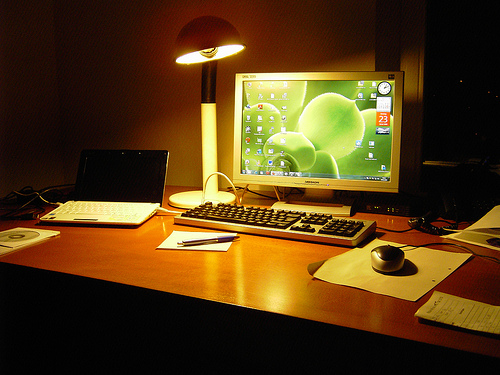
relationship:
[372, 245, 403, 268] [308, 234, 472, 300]
mouse on top of paper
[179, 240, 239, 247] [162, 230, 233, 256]
pen on top of paper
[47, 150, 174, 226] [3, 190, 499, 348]
laptop on desk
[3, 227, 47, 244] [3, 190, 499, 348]
cd on desk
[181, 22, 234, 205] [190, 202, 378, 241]
lamp shining on keyboard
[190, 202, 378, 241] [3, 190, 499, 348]
keyboard on desk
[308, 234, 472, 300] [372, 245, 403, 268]
paper under mouse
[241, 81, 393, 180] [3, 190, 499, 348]
computer on desk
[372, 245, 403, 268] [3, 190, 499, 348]
mouse on desk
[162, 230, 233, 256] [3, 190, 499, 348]
notebook on desk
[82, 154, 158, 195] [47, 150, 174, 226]
screen on laptop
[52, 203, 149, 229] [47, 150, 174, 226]
keyboard on laptop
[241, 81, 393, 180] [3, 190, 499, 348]
monitor on desk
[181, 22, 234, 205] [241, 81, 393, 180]
lamp over desktop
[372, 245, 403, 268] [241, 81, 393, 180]
mouse in front of desktop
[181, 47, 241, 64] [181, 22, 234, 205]
light on lamp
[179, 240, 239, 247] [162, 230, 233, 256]
pen on notebook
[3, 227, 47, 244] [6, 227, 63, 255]
cd in white case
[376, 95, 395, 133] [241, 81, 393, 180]
calender on desktop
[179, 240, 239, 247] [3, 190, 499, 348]
pen laying on top of desk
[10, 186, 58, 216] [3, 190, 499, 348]
cords on desk